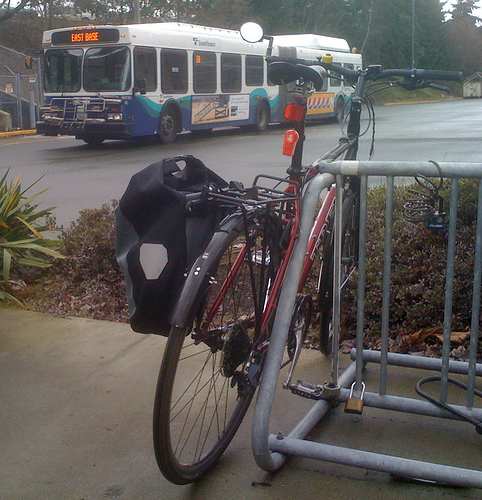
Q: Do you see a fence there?
A: Yes, there is a fence.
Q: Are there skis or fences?
A: Yes, there is a fence.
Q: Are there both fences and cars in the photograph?
A: No, there is a fence but no cars.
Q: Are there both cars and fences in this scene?
A: No, there is a fence but no cars.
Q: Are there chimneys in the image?
A: No, there are no chimneys.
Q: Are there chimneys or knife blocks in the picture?
A: No, there are no chimneys or knife blocks.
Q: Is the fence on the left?
A: Yes, the fence is on the left of the image.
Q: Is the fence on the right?
A: No, the fence is on the left of the image.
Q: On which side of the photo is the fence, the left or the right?
A: The fence is on the left of the image.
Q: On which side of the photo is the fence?
A: The fence is on the left of the image.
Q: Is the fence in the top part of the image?
A: Yes, the fence is in the top of the image.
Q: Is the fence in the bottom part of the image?
A: No, the fence is in the top of the image.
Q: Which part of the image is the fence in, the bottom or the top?
A: The fence is in the top of the image.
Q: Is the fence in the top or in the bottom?
A: The fence is in the top of the image.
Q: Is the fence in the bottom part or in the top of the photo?
A: The fence is in the top of the image.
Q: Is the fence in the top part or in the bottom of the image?
A: The fence is in the top of the image.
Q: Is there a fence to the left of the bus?
A: Yes, there is a fence to the left of the bus.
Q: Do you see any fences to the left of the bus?
A: Yes, there is a fence to the left of the bus.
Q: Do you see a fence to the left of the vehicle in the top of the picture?
A: Yes, there is a fence to the left of the bus.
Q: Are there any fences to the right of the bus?
A: No, the fence is to the left of the bus.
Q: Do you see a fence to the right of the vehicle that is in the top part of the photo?
A: No, the fence is to the left of the bus.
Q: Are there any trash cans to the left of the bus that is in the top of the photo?
A: No, there is a fence to the left of the bus.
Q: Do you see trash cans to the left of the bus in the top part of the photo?
A: No, there is a fence to the left of the bus.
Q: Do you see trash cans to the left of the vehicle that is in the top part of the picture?
A: No, there is a fence to the left of the bus.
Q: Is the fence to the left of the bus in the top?
A: Yes, the fence is to the left of the bus.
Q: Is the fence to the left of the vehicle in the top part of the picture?
A: Yes, the fence is to the left of the bus.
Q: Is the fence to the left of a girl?
A: No, the fence is to the left of the bus.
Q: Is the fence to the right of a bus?
A: No, the fence is to the left of a bus.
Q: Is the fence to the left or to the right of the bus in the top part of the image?
A: The fence is to the left of the bus.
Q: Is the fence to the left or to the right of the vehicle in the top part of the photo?
A: The fence is to the left of the bus.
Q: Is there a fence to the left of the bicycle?
A: Yes, there is a fence to the left of the bicycle.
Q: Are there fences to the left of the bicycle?
A: Yes, there is a fence to the left of the bicycle.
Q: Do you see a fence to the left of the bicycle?
A: Yes, there is a fence to the left of the bicycle.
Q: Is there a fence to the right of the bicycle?
A: No, the fence is to the left of the bicycle.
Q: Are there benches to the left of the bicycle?
A: No, there is a fence to the left of the bicycle.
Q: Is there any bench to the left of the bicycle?
A: No, there is a fence to the left of the bicycle.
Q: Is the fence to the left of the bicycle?
A: Yes, the fence is to the left of the bicycle.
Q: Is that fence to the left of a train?
A: No, the fence is to the left of the bicycle.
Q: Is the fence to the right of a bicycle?
A: No, the fence is to the left of a bicycle.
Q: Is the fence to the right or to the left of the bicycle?
A: The fence is to the left of the bicycle.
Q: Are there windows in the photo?
A: Yes, there is a window.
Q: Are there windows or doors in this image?
A: Yes, there is a window.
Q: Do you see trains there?
A: No, there are no trains.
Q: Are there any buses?
A: Yes, there is a bus.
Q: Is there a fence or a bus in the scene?
A: Yes, there is a bus.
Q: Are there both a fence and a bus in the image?
A: Yes, there are both a bus and a fence.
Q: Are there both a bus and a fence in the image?
A: Yes, there are both a bus and a fence.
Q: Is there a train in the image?
A: No, there are no trains.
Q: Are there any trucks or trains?
A: No, there are no trains or trucks.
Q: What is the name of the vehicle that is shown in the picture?
A: The vehicle is a bus.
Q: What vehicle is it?
A: The vehicle is a bus.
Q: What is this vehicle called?
A: This is a bus.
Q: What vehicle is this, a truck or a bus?
A: This is a bus.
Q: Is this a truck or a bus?
A: This is a bus.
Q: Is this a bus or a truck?
A: This is a bus.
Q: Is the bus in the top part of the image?
A: Yes, the bus is in the top of the image.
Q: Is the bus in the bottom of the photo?
A: No, the bus is in the top of the image.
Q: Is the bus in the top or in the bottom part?
A: The bus is in the top of the image.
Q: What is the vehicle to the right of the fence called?
A: The vehicle is a bus.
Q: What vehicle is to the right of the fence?
A: The vehicle is a bus.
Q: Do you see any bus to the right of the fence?
A: Yes, there is a bus to the right of the fence.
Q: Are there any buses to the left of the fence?
A: No, the bus is to the right of the fence.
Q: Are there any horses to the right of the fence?
A: No, there is a bus to the right of the fence.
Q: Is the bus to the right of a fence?
A: Yes, the bus is to the right of a fence.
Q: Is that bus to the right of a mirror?
A: No, the bus is to the right of a fence.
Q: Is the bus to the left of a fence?
A: No, the bus is to the right of a fence.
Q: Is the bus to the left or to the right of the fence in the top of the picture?
A: The bus is to the right of the fence.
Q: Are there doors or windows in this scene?
A: Yes, there are windows.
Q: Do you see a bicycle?
A: Yes, there is a bicycle.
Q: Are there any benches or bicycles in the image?
A: Yes, there is a bicycle.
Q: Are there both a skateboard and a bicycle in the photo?
A: No, there is a bicycle but no skateboards.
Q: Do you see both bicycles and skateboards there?
A: No, there is a bicycle but no skateboards.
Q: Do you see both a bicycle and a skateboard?
A: No, there is a bicycle but no skateboards.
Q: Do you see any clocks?
A: No, there are no clocks.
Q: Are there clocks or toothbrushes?
A: No, there are no clocks or toothbrushes.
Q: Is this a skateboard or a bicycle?
A: This is a bicycle.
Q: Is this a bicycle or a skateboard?
A: This is a bicycle.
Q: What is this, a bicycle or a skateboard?
A: This is a bicycle.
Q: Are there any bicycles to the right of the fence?
A: Yes, there is a bicycle to the right of the fence.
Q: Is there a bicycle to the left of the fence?
A: No, the bicycle is to the right of the fence.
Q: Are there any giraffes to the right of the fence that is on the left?
A: No, there is a bicycle to the right of the fence.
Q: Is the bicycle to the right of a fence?
A: Yes, the bicycle is to the right of a fence.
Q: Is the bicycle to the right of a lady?
A: No, the bicycle is to the right of a fence.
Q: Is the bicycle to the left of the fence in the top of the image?
A: No, the bicycle is to the right of the fence.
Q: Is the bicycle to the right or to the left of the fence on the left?
A: The bicycle is to the right of the fence.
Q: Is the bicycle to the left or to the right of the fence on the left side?
A: The bicycle is to the right of the fence.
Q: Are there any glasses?
A: No, there are no glasses.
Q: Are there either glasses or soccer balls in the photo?
A: No, there are no glasses or soccer balls.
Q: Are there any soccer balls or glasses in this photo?
A: No, there are no glasses or soccer balls.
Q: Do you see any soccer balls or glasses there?
A: No, there are no glasses or soccer balls.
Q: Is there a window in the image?
A: Yes, there are windows.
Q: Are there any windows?
A: Yes, there are windows.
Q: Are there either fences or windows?
A: Yes, there are windows.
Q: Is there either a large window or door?
A: Yes, there are large windows.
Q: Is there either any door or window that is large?
A: Yes, the windows are large.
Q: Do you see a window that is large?
A: Yes, there are large windows.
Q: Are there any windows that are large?
A: Yes, there are windows that are large.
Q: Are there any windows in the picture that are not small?
A: Yes, there are large windows.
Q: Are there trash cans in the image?
A: No, there are no trash cans.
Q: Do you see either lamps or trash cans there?
A: No, there are no trash cans or lamps.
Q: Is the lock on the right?
A: Yes, the lock is on the right of the image.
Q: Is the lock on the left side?
A: No, the lock is on the right of the image.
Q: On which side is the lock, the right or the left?
A: The lock is on the right of the image.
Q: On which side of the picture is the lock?
A: The lock is on the right of the image.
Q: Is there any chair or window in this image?
A: Yes, there is a window.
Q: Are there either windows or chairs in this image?
A: Yes, there is a window.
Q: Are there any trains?
A: No, there are no trains.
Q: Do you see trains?
A: No, there are no trains.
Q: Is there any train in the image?
A: No, there are no trains.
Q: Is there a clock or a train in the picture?
A: No, there are no trains or clocks.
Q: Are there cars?
A: No, there are no cars.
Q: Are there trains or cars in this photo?
A: No, there are no cars or trains.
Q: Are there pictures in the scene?
A: No, there are no pictures.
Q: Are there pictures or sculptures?
A: No, there are no pictures or sculptures.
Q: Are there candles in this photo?
A: No, there are no candles.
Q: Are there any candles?
A: No, there are no candles.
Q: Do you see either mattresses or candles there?
A: No, there are no candles or mattresses.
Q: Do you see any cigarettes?
A: No, there are no cigarettes.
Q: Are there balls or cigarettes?
A: No, there are no cigarettes or balls.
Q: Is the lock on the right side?
A: Yes, the lock is on the right of the image.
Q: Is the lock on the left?
A: No, the lock is on the right of the image.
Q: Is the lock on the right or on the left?
A: The lock is on the right of the image.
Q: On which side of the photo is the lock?
A: The lock is on the right of the image.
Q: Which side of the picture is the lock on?
A: The lock is on the right of the image.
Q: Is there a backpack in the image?
A: Yes, there is a backpack.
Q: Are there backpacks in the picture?
A: Yes, there is a backpack.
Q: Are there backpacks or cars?
A: Yes, there is a backpack.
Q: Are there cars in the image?
A: No, there are no cars.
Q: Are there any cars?
A: No, there are no cars.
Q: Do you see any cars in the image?
A: No, there are no cars.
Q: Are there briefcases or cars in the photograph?
A: No, there are no cars or briefcases.